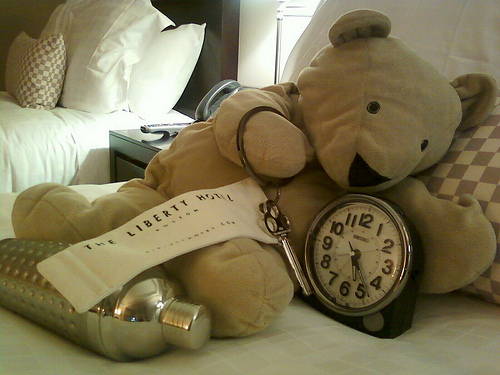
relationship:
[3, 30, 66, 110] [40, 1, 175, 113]
pillow leaning on pillow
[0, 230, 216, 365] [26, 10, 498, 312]
bottle on teddy bear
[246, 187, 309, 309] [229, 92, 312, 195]
key around wrist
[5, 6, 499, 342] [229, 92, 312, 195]
bear has wrist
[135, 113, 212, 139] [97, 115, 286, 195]
remote control on nightstand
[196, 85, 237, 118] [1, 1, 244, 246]
telephone next to bed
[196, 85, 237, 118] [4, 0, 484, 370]
telephone next to bed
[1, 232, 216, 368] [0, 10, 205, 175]
bottle on bed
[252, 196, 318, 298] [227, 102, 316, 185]
key on hand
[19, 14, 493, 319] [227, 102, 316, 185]
bear has hand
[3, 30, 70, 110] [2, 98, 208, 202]
pillow on bed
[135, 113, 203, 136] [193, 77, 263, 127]
remote control next to telephone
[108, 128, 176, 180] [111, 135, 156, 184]
nightstand with drawer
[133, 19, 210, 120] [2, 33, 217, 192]
pillow on bed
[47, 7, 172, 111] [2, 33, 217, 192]
pillow on bed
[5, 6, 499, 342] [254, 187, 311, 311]
bear holding key ring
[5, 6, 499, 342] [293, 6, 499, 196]
bear laying head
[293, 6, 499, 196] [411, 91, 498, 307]
head on pillow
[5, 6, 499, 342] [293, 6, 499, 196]
bear has head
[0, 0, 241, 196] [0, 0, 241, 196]
bed with bed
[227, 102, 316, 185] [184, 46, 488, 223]
hand of bear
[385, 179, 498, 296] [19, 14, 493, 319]
hand of bear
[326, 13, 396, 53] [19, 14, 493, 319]
ear of bear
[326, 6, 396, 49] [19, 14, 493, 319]
ear of bear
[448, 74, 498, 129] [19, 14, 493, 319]
ear of bear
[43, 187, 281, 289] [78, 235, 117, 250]
label with word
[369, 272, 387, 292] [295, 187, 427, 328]
number on clock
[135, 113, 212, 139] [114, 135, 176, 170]
remote control on drawer